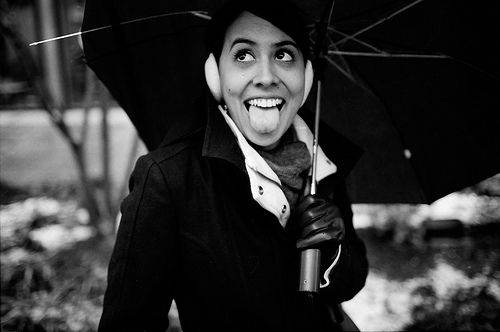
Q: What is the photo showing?
A: It is showing a pond.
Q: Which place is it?
A: It is a pond.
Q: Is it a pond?
A: Yes, it is a pond.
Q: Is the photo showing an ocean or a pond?
A: It is showing a pond.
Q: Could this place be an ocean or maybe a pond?
A: It is a pond.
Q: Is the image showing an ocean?
A: No, the picture is showing a pond.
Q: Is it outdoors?
A: Yes, it is outdoors.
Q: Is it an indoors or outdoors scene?
A: It is outdoors.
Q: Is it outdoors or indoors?
A: It is outdoors.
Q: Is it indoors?
A: No, it is outdoors.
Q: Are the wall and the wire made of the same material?
A: No, the wall is made of concrete and the wire is made of metal.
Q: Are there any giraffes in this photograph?
A: No, there are no giraffes.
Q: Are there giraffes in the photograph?
A: No, there are no giraffes.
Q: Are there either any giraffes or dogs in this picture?
A: No, there are no giraffes or dogs.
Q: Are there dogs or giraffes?
A: No, there are no giraffes or dogs.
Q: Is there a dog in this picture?
A: No, there are no dogs.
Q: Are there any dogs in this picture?
A: No, there are no dogs.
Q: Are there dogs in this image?
A: No, there are no dogs.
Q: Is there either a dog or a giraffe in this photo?
A: No, there are no dogs or giraffes.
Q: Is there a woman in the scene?
A: Yes, there is a woman.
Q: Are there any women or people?
A: Yes, there is a woman.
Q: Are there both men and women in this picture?
A: No, there is a woman but no men.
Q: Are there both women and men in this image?
A: No, there is a woman but no men.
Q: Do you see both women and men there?
A: No, there is a woman but no men.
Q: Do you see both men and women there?
A: No, there is a woman but no men.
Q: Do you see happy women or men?
A: Yes, there is a happy woman.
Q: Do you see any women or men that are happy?
A: Yes, the woman is happy.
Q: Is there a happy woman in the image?
A: Yes, there is a happy woman.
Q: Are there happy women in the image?
A: Yes, there is a happy woman.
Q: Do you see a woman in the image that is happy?
A: Yes, there is a woman that is happy.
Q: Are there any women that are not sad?
A: Yes, there is a happy woman.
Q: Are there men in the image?
A: No, there are no men.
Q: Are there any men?
A: No, there are no men.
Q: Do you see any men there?
A: No, there are no men.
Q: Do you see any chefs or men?
A: No, there are no men or chefs.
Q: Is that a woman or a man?
A: That is a woman.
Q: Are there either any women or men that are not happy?
A: No, there is a woman but she is happy.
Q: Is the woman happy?
A: Yes, the woman is happy.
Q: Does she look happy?
A: Yes, the woman is happy.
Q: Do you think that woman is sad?
A: No, the woman is happy.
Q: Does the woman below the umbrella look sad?
A: No, the woman is happy.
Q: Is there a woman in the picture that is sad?
A: No, there is a woman but she is happy.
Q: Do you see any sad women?
A: No, there is a woman but she is happy.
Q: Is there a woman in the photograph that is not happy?
A: No, there is a woman but she is happy.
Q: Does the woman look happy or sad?
A: The woman is happy.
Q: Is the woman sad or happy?
A: The woman is happy.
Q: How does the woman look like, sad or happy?
A: The woman is happy.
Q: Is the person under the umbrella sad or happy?
A: The woman is happy.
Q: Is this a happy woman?
A: Yes, this is a happy woman.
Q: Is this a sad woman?
A: No, this is a happy woman.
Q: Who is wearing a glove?
A: The woman is wearing a glove.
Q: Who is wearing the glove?
A: The woman is wearing a glove.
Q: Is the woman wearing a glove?
A: Yes, the woman is wearing a glove.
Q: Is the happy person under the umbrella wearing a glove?
A: Yes, the woman is wearing a glove.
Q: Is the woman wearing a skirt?
A: No, the woman is wearing a glove.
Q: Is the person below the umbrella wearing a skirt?
A: No, the woman is wearing a glove.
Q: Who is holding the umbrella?
A: The woman is holding the umbrella.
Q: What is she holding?
A: The woman is holding the umbrella.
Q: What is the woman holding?
A: The woman is holding the umbrella.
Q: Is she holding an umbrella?
A: Yes, the woman is holding an umbrella.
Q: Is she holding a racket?
A: No, the woman is holding an umbrella.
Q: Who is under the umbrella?
A: The woman is under the umbrella.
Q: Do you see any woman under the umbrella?
A: Yes, there is a woman under the umbrella.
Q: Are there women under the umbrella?
A: Yes, there is a woman under the umbrella.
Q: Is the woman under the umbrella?
A: Yes, the woman is under the umbrella.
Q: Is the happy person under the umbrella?
A: Yes, the woman is under the umbrella.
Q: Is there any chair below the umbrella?
A: No, there is a woman below the umbrella.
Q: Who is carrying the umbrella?
A: The woman is carrying the umbrella.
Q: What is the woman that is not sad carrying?
A: The woman is carrying an umbrella.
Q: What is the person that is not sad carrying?
A: The woman is carrying an umbrella.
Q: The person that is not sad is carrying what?
A: The woman is carrying an umbrella.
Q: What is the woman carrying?
A: The woman is carrying an umbrella.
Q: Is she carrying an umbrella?
A: Yes, the woman is carrying an umbrella.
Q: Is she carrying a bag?
A: No, the woman is carrying an umbrella.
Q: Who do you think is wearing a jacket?
A: The woman is wearing a jacket.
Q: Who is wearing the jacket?
A: The woman is wearing a jacket.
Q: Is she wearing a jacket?
A: Yes, the woman is wearing a jacket.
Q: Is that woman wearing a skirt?
A: No, the woman is wearing a jacket.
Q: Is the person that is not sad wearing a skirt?
A: No, the woman is wearing a jacket.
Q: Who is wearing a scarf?
A: The woman is wearing a scarf.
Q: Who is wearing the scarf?
A: The woman is wearing a scarf.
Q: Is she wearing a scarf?
A: Yes, the woman is wearing a scarf.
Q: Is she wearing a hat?
A: No, the woman is wearing a scarf.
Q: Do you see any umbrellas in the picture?
A: Yes, there is an umbrella.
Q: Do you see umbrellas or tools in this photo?
A: Yes, there is an umbrella.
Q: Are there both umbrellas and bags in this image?
A: No, there is an umbrella but no bags.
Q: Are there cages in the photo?
A: No, there are no cages.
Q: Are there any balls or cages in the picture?
A: No, there are no cages or balls.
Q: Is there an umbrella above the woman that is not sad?
A: Yes, there is an umbrella above the woman.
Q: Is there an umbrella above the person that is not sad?
A: Yes, there is an umbrella above the woman.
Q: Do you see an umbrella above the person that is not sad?
A: Yes, there is an umbrella above the woman.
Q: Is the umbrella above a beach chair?
A: No, the umbrella is above the woman.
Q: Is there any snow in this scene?
A: Yes, there is snow.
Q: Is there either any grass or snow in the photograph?
A: Yes, there is snow.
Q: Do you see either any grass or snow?
A: Yes, there is snow.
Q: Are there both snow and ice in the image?
A: No, there is snow but no ice.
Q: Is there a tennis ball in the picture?
A: No, there are no tennis balls.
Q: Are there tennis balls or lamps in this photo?
A: No, there are no tennis balls or lamps.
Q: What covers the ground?
A: The snow covers the ground.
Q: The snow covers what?
A: The snow covers the ground.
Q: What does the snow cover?
A: The snow covers the ground.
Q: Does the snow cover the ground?
A: Yes, the snow covers the ground.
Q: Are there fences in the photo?
A: No, there are no fences.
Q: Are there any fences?
A: No, there are no fences.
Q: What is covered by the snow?
A: The ground is covered by the snow.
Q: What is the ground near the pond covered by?
A: The ground is covered by the snow.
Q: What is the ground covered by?
A: The ground is covered by the snow.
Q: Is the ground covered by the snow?
A: Yes, the ground is covered by the snow.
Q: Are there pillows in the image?
A: No, there are no pillows.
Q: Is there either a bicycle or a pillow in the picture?
A: No, there are no pillows or bicycles.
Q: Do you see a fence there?
A: No, there are no fences.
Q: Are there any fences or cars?
A: No, there are no fences or cars.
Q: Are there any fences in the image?
A: No, there are no fences.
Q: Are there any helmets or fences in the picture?
A: No, there are no fences or helmets.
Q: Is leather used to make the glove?
A: Yes, the glove is made of leather.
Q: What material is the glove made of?
A: The glove is made of leather.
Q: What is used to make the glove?
A: The glove is made of leather.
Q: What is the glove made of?
A: The glove is made of leather.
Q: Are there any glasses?
A: No, there are no glasses.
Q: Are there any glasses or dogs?
A: No, there are no glasses or dogs.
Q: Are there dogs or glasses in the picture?
A: No, there are no glasses or dogs.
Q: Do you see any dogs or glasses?
A: No, there are no glasses or dogs.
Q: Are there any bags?
A: No, there are no bags.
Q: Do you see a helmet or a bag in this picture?
A: No, there are no bags or helmets.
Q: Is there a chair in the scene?
A: No, there are no chairs.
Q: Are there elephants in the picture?
A: No, there are no elephants.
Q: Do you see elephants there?
A: No, there are no elephants.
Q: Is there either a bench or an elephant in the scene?
A: No, there are no elephants or benches.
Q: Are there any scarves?
A: Yes, there is a scarf.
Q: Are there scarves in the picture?
A: Yes, there is a scarf.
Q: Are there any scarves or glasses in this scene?
A: Yes, there is a scarf.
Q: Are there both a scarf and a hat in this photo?
A: No, there is a scarf but no hats.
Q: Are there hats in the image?
A: No, there are no hats.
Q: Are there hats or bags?
A: No, there are no hats or bags.